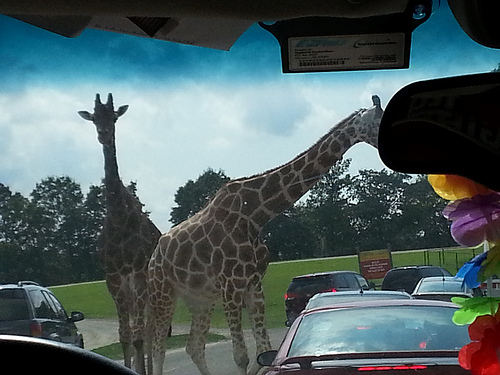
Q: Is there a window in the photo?
A: Yes, there are windows.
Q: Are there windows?
A: Yes, there are windows.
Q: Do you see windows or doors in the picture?
A: Yes, there are windows.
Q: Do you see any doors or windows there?
A: Yes, there are windows.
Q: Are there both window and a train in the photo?
A: No, there are windows but no trains.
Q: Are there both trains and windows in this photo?
A: No, there are windows but no trains.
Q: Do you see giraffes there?
A: Yes, there is a giraffe.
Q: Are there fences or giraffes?
A: Yes, there is a giraffe.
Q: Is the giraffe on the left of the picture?
A: Yes, the giraffe is on the left of the image.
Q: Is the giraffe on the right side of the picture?
A: No, the giraffe is on the left of the image.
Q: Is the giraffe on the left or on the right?
A: The giraffe is on the left of the image.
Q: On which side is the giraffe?
A: The giraffe is on the left of the image.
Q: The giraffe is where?
A: The giraffe is on the road.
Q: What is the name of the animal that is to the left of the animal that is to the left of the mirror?
A: The animal is a giraffe.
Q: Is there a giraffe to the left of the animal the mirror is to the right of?
A: Yes, there is a giraffe to the left of the animal.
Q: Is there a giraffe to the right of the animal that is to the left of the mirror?
A: No, the giraffe is to the left of the animal.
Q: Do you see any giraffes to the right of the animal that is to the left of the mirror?
A: No, the giraffe is to the left of the animal.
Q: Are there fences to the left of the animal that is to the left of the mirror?
A: No, there is a giraffe to the left of the animal.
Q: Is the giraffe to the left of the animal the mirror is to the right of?
A: Yes, the giraffe is to the left of the animal.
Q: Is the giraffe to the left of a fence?
A: No, the giraffe is to the left of the animal.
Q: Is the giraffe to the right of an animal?
A: No, the giraffe is to the left of an animal.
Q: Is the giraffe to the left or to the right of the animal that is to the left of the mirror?
A: The giraffe is to the left of the animal.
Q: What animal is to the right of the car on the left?
A: The animal is a giraffe.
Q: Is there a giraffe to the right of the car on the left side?
A: Yes, there is a giraffe to the right of the car.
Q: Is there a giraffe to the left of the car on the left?
A: No, the giraffe is to the right of the car.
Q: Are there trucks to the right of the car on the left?
A: No, there is a giraffe to the right of the car.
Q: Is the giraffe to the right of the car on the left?
A: Yes, the giraffe is to the right of the car.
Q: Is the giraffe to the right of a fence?
A: No, the giraffe is to the right of the car.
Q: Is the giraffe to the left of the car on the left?
A: No, the giraffe is to the right of the car.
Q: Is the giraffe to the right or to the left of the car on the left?
A: The giraffe is to the right of the car.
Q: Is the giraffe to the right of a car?
A: No, the giraffe is to the left of a car.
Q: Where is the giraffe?
A: The giraffe is on the road.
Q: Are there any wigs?
A: No, there are no wigs.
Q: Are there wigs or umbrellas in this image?
A: No, there are no wigs or umbrellas.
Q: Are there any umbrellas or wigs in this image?
A: No, there are no wigs or umbrellas.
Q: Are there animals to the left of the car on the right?
A: Yes, there is an animal to the left of the car.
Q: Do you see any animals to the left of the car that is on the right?
A: Yes, there is an animal to the left of the car.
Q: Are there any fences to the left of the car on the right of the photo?
A: No, there is an animal to the left of the car.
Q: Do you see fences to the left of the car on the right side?
A: No, there is an animal to the left of the car.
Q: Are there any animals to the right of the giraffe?
A: Yes, there is an animal to the right of the giraffe.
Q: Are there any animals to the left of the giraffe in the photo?
A: No, the animal is to the right of the giraffe.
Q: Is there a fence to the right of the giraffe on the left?
A: No, there is an animal to the right of the giraffe.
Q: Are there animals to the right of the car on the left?
A: Yes, there is an animal to the right of the car.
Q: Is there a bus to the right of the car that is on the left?
A: No, there is an animal to the right of the car.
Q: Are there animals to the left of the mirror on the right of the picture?
A: Yes, there is an animal to the left of the mirror.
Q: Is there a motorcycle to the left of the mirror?
A: No, there is an animal to the left of the mirror.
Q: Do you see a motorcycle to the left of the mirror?
A: No, there is an animal to the left of the mirror.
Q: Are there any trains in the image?
A: No, there are no trains.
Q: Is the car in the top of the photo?
A: No, the car is in the bottom of the image.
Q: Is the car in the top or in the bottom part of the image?
A: The car is in the bottom of the image.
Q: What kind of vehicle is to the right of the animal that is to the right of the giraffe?
A: The vehicle is a car.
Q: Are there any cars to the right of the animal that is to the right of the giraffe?
A: Yes, there is a car to the right of the animal.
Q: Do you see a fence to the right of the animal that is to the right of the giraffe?
A: No, there is a car to the right of the animal.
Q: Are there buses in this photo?
A: No, there are no buses.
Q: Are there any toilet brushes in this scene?
A: No, there are no toilet brushes.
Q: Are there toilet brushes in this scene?
A: No, there are no toilet brushes.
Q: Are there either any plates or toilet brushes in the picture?
A: No, there are no toilet brushes or plates.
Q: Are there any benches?
A: No, there are no benches.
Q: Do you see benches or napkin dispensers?
A: No, there are no benches or napkin dispensers.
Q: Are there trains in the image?
A: No, there are no trains.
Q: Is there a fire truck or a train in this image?
A: No, there are no trains or fire trucks.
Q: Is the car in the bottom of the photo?
A: Yes, the car is in the bottom of the image.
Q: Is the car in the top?
A: No, the car is in the bottom of the image.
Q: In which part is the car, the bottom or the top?
A: The car is in the bottom of the image.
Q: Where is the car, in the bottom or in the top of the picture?
A: The car is in the bottom of the image.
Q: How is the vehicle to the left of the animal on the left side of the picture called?
A: The vehicle is a car.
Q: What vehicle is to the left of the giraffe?
A: The vehicle is a car.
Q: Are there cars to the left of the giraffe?
A: Yes, there is a car to the left of the giraffe.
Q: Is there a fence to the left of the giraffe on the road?
A: No, there is a car to the left of the giraffe.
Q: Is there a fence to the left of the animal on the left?
A: No, there is a car to the left of the giraffe.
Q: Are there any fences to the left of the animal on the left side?
A: No, there is a car to the left of the giraffe.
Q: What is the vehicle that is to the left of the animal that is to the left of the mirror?
A: The vehicle is a car.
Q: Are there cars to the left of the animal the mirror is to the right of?
A: Yes, there is a car to the left of the animal.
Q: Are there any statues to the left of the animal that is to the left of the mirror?
A: No, there is a car to the left of the animal.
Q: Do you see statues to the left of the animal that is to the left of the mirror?
A: No, there is a car to the left of the animal.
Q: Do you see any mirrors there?
A: Yes, there is a mirror.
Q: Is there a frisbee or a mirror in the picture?
A: Yes, there is a mirror.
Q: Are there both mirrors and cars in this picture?
A: Yes, there are both a mirror and a car.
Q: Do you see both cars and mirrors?
A: Yes, there are both a mirror and a car.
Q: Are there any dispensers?
A: No, there are no dispensers.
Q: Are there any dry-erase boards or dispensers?
A: No, there are no dispensers or dry-erase boards.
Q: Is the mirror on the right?
A: Yes, the mirror is on the right of the image.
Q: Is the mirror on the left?
A: No, the mirror is on the right of the image.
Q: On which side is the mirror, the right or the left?
A: The mirror is on the right of the image.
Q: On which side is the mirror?
A: The mirror is on the right of the image.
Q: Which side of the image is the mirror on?
A: The mirror is on the right of the image.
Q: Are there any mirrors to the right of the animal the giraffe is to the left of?
A: Yes, there is a mirror to the right of the animal.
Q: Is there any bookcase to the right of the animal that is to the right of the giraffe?
A: No, there is a mirror to the right of the animal.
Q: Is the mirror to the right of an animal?
A: Yes, the mirror is to the right of an animal.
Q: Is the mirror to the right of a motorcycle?
A: No, the mirror is to the right of an animal.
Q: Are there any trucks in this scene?
A: No, there are no trucks.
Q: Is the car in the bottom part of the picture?
A: Yes, the car is in the bottom of the image.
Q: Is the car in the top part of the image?
A: No, the car is in the bottom of the image.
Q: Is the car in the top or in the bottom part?
A: The car is in the bottom of the image.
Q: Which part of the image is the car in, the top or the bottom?
A: The car is in the bottom of the image.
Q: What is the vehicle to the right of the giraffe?
A: The vehicle is a car.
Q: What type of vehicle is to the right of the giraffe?
A: The vehicle is a car.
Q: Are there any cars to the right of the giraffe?
A: Yes, there is a car to the right of the giraffe.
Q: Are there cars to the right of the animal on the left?
A: Yes, there is a car to the right of the giraffe.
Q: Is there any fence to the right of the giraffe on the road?
A: No, there is a car to the right of the giraffe.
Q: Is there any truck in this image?
A: No, there are no trucks.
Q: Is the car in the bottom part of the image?
A: Yes, the car is in the bottom of the image.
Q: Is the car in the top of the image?
A: No, the car is in the bottom of the image.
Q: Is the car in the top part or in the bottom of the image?
A: The car is in the bottom of the image.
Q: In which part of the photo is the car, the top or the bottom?
A: The car is in the bottom of the image.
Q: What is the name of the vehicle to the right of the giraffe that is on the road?
A: The vehicle is a car.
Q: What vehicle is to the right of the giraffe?
A: The vehicle is a car.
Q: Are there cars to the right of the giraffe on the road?
A: Yes, there is a car to the right of the giraffe.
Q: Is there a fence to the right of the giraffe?
A: No, there is a car to the right of the giraffe.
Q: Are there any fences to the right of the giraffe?
A: No, there is a car to the right of the giraffe.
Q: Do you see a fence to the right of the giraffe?
A: No, there is a car to the right of the giraffe.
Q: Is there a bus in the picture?
A: No, there are no buses.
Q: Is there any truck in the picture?
A: No, there are no trucks.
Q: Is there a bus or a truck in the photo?
A: No, there are no trucks or buses.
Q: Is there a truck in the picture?
A: No, there are no trucks.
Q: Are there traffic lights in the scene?
A: No, there are no traffic lights.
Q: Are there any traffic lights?
A: No, there are no traffic lights.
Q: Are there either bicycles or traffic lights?
A: No, there are no traffic lights or bicycles.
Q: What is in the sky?
A: The clouds are in the sky.